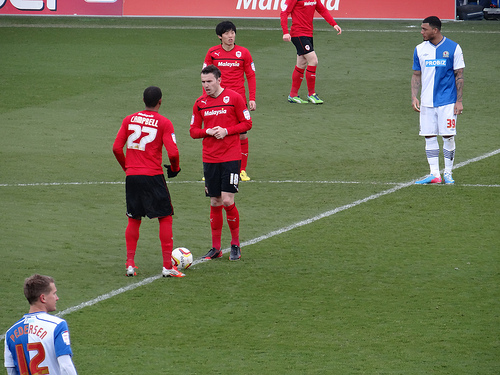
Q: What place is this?
A: It is a field.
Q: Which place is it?
A: It is a field.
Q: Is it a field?
A: Yes, it is a field.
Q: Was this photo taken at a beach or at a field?
A: It was taken at a field.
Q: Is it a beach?
A: No, it is a field.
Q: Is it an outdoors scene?
A: Yes, it is outdoors.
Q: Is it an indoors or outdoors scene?
A: It is outdoors.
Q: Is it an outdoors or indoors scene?
A: It is outdoors.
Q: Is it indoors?
A: No, it is outdoors.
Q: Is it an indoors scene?
A: No, it is outdoors.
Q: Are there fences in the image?
A: No, there are no fences.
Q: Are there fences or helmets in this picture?
A: No, there are no fences or helmets.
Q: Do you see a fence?
A: No, there are no fences.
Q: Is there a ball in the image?
A: Yes, there is a ball.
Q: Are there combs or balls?
A: Yes, there is a ball.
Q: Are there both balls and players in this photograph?
A: Yes, there are both a ball and a player.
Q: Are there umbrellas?
A: No, there are no umbrellas.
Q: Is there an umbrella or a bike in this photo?
A: No, there are no umbrellas or bikes.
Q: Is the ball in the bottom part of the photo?
A: Yes, the ball is in the bottom of the image.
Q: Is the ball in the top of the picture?
A: No, the ball is in the bottom of the image.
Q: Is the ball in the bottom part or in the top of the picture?
A: The ball is in the bottom of the image.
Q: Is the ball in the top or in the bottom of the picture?
A: The ball is in the bottom of the image.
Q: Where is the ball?
A: The ball is on the field.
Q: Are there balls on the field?
A: Yes, there is a ball on the field.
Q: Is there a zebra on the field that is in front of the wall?
A: No, there is a ball on the field.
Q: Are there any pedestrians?
A: No, there are no pedestrians.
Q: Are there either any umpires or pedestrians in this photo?
A: No, there are no pedestrians or umpires.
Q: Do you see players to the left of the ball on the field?
A: Yes, there is a player to the left of the ball.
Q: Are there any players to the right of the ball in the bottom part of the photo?
A: No, the player is to the left of the ball.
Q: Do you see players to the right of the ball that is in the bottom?
A: No, the player is to the left of the ball.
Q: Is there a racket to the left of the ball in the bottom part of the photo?
A: No, there is a player to the left of the ball.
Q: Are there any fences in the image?
A: No, there are no fences.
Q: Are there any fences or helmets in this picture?
A: No, there are no fences or helmets.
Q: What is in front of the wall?
A: The field is in front of the wall.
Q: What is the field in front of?
A: The field is in front of the wall.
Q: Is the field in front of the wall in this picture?
A: Yes, the field is in front of the wall.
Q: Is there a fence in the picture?
A: No, there are no fences.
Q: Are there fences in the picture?
A: No, there are no fences.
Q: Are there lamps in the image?
A: No, there are no lamps.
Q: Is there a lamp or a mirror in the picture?
A: No, there are no lamps or mirrors.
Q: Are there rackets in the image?
A: No, there are no rackets.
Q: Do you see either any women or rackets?
A: No, there are no rackets or women.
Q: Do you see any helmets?
A: No, there are no helmets.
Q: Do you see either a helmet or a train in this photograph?
A: No, there are no helmets or trains.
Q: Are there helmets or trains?
A: No, there are no helmets or trains.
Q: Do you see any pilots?
A: No, there are no pilots.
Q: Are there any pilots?
A: No, there are no pilots.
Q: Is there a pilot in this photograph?
A: No, there are no pilots.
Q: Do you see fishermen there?
A: No, there are no fishermen.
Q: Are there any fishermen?
A: No, there are no fishermen.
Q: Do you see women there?
A: No, there are no women.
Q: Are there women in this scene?
A: No, there are no women.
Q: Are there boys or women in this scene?
A: No, there are no women or boys.